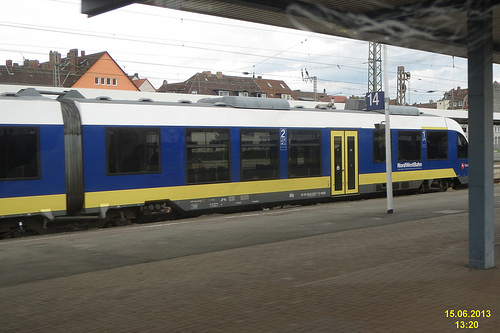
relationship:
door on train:
[331, 130, 345, 196] [117, 85, 374, 200]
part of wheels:
[439, 180, 444, 186] [0, 175, 463, 235]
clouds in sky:
[216, 30, 346, 73] [4, 5, 495, 105]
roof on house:
[164, 64, 265, 95] [159, 77, 263, 103]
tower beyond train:
[391, 68, 445, 123] [0, 77, 480, 248]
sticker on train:
[455, 161, 470, 173] [166, 85, 472, 202]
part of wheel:
[139, 204, 166, 214] [135, 202, 168, 212]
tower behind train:
[366, 37, 385, 100] [0, 77, 480, 248]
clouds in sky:
[84, 8, 454, 86] [4, 5, 495, 105]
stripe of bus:
[0, 159, 458, 219] [6, 72, 468, 218]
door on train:
[331, 130, 345, 196] [28, 43, 482, 261]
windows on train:
[100, 126, 320, 191] [0, 77, 480, 248]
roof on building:
[3, 50, 138, 86] [0, 51, 137, 91]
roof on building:
[5, 48, 107, 86] [11, 55, 152, 92]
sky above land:
[146, 18, 254, 69] [0, 141, 497, 331]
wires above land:
[150, 24, 227, 87] [6, 94, 497, 328]